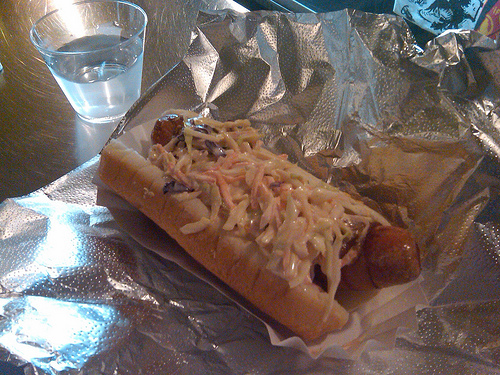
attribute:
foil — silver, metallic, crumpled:
[1, 8, 498, 374]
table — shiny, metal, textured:
[1, 1, 241, 203]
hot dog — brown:
[152, 114, 420, 289]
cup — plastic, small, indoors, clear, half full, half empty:
[30, 1, 153, 122]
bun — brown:
[92, 107, 391, 340]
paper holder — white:
[92, 107, 430, 359]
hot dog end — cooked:
[339, 225, 424, 288]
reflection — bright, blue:
[1, 192, 119, 373]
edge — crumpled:
[197, 9, 498, 96]